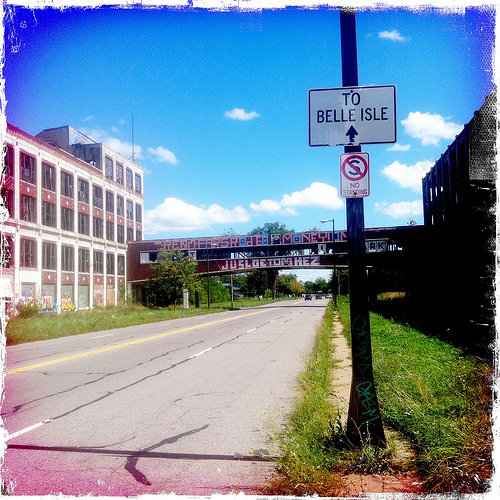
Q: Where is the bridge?
A: End of building.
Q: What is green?
A: Grass.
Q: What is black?
A: Pole.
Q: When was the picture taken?
A: Daytime.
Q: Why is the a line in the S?
A: No skating.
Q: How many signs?
A: Two.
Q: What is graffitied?
A: Bridge.